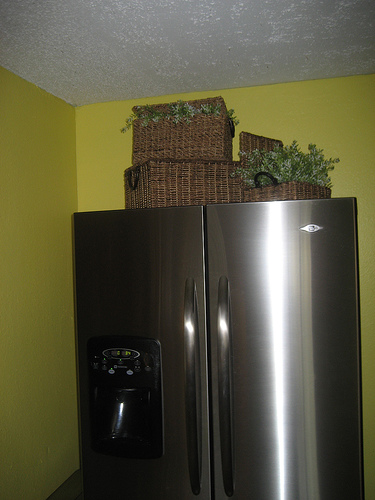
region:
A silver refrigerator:
[69, 199, 362, 498]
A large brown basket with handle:
[123, 159, 243, 199]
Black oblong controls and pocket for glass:
[82, 332, 170, 469]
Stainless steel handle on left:
[179, 278, 204, 498]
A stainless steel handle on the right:
[212, 271, 254, 498]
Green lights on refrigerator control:
[100, 342, 142, 365]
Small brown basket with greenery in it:
[234, 160, 324, 197]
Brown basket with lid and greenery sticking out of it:
[126, 83, 239, 160]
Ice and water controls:
[84, 335, 171, 385]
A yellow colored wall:
[4, 106, 69, 469]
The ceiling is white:
[20, 10, 350, 92]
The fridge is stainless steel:
[54, 234, 358, 409]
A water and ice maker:
[77, 335, 203, 498]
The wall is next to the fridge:
[0, 218, 112, 486]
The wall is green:
[7, 249, 140, 429]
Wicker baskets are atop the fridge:
[116, 106, 342, 239]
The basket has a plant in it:
[223, 145, 367, 195]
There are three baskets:
[127, 98, 354, 205]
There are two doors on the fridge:
[129, 263, 274, 464]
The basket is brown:
[112, 153, 289, 219]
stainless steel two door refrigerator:
[70, 195, 363, 498]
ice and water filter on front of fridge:
[83, 333, 168, 461]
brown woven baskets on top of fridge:
[119, 91, 341, 209]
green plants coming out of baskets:
[119, 98, 341, 187]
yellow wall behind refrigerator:
[0, 60, 374, 498]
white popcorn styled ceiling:
[2, 0, 374, 106]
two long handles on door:
[180, 274, 238, 499]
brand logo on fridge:
[298, 223, 324, 234]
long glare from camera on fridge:
[261, 201, 293, 499]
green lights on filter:
[91, 346, 141, 364]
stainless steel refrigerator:
[72, 196, 359, 498]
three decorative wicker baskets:
[124, 96, 329, 203]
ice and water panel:
[90, 338, 164, 459]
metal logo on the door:
[300, 223, 323, 232]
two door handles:
[184, 276, 233, 496]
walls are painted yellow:
[2, 68, 373, 497]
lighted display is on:
[102, 348, 138, 359]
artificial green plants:
[235, 141, 339, 187]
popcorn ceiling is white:
[0, 6, 369, 106]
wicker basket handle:
[127, 166, 139, 189]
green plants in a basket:
[238, 144, 340, 186]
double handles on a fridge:
[182, 272, 241, 499]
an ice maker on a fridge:
[89, 332, 166, 458]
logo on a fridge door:
[296, 216, 331, 237]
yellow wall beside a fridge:
[17, 210, 58, 286]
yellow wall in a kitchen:
[16, 235, 62, 342]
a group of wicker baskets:
[121, 94, 321, 209]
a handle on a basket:
[123, 163, 145, 193]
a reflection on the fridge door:
[250, 213, 305, 493]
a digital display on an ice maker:
[104, 345, 141, 363]